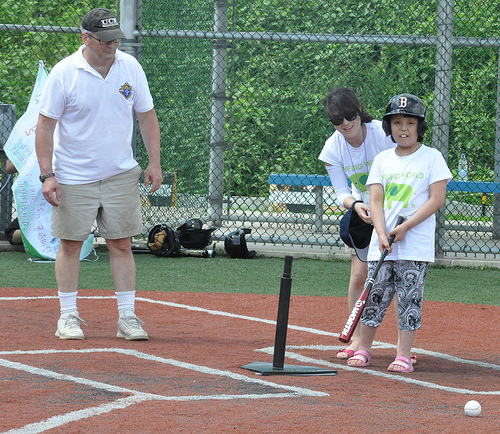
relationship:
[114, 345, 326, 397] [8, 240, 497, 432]
line on field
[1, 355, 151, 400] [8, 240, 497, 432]
line on field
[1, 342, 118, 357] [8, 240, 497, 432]
line on field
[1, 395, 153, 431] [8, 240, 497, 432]
line on field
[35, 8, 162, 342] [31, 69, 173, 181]
man wearing a shirt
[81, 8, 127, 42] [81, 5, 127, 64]
cap on head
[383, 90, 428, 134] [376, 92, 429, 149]
helmet on head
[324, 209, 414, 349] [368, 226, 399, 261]
bat in hand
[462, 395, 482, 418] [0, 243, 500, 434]
ball on field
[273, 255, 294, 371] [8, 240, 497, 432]
pole on field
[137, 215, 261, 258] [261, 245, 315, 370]
bags by pole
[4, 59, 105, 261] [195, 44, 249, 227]
bags by pole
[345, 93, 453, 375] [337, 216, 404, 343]
girl has bat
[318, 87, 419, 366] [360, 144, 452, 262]
girl wearing shirt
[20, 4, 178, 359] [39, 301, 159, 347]
man wearing shoes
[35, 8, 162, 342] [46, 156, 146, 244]
man wearing shorts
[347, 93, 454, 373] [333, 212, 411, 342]
girl holding bat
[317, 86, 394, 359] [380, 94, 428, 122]
girl wearing helmet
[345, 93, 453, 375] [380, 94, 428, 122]
girl wearing helmet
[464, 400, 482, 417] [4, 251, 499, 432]
ball lying on ground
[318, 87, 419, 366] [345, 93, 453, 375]
girl standing behind girl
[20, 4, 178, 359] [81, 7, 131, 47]
man wearing cap